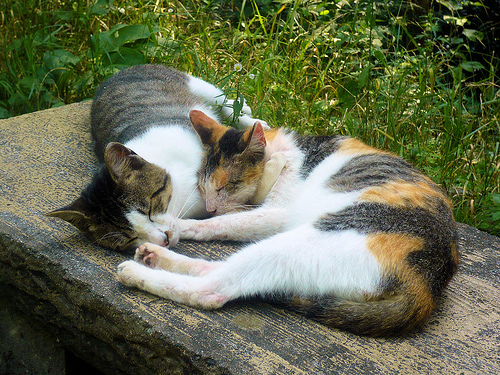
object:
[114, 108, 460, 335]
cats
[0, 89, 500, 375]
bench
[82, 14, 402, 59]
vegetation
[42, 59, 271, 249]
cat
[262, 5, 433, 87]
weeds